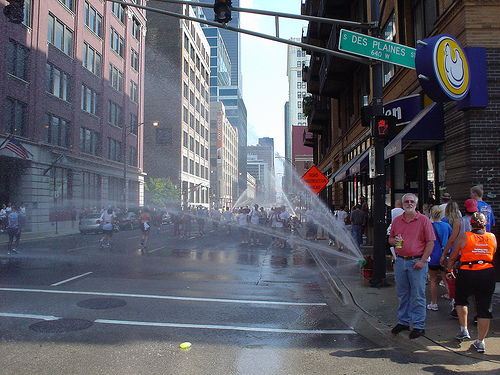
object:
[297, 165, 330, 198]
sign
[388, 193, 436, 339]
man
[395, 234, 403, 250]
bottle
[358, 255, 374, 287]
hydrant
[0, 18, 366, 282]
water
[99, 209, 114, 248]
people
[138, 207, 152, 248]
people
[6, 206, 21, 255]
people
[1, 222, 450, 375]
street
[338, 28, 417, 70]
sign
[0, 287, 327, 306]
lines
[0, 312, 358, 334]
lines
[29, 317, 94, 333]
covers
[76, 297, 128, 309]
covers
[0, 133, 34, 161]
flag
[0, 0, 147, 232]
building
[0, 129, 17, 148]
pole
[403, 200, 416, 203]
glasses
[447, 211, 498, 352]
woman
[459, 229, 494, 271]
shirt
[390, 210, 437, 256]
shirt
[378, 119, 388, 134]
signal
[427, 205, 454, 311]
woman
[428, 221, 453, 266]
shirt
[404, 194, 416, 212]
face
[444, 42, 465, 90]
logo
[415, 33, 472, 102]
sign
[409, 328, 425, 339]
shoe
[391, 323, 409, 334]
shoe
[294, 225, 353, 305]
curb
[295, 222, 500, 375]
sidewalk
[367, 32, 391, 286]
pole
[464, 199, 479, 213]
cap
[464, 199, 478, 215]
head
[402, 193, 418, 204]
hair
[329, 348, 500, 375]
shadow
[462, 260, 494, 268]
band